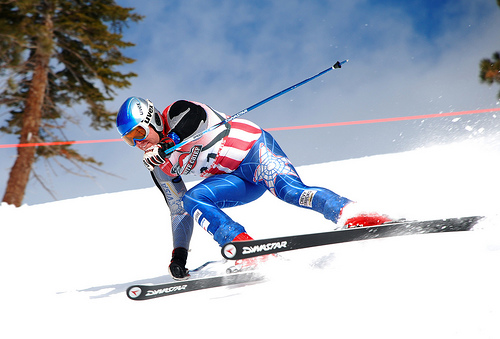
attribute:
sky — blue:
[242, 13, 355, 31]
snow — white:
[3, 149, 491, 317]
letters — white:
[145, 283, 190, 295]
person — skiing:
[113, 94, 393, 269]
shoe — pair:
[336, 202, 402, 239]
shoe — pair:
[226, 232, 286, 277]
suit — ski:
[113, 91, 401, 276]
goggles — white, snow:
[122, 98, 156, 144]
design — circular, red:
[221, 243, 239, 260]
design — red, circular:
[121, 280, 146, 300]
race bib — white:
[191, 146, 223, 177]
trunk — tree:
[0, 0, 117, 200]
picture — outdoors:
[7, 5, 499, 335]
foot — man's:
[336, 204, 397, 236]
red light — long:
[1, 102, 498, 152]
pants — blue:
[178, 150, 391, 244]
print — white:
[238, 239, 292, 255]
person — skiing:
[110, 92, 487, 302]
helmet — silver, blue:
[89, 86, 214, 153]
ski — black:
[218, 210, 488, 258]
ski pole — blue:
[157, 52, 348, 163]